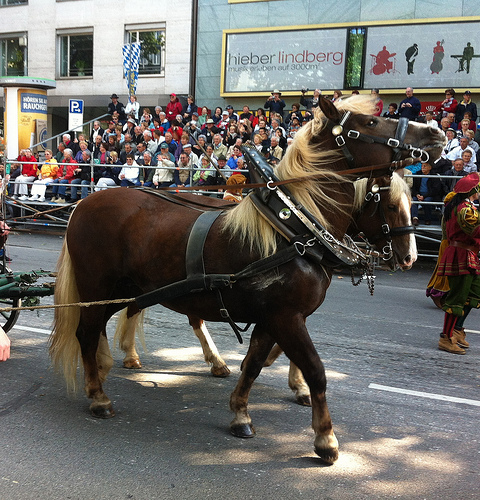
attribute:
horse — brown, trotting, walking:
[47, 91, 449, 464]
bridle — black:
[234, 143, 381, 285]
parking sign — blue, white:
[68, 97, 85, 117]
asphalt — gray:
[0, 217, 466, 490]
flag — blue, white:
[117, 45, 148, 81]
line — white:
[367, 373, 479, 422]